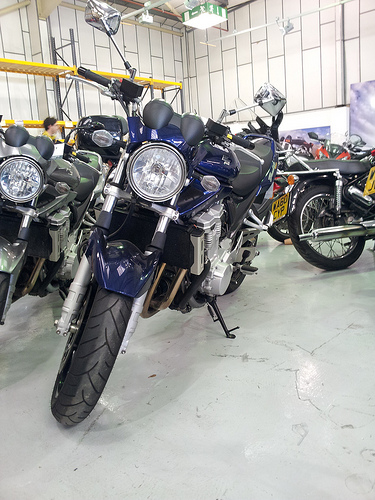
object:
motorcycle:
[50, 67, 277, 427]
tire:
[50, 275, 131, 431]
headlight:
[129, 142, 184, 206]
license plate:
[270, 194, 288, 222]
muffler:
[295, 221, 371, 242]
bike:
[52, 65, 277, 430]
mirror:
[86, 4, 121, 37]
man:
[42, 118, 64, 141]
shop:
[1, 2, 374, 495]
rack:
[2, 55, 179, 94]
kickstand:
[205, 295, 235, 338]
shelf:
[1, 55, 182, 92]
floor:
[3, 226, 373, 497]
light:
[180, 5, 226, 33]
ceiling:
[114, 2, 247, 24]